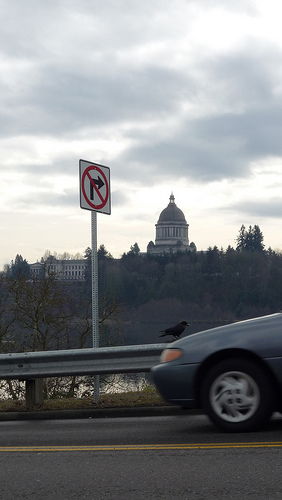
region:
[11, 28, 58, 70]
white clouds in blue sky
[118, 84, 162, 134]
white clouds in blue sky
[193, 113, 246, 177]
white clouds in blue sky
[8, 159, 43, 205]
white clouds in blue sky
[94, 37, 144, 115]
white clouds in blue sky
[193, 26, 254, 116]
white clouds in blue sky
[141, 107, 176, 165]
white clouds in blue sky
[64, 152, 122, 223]
black white and red sign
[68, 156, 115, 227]
black red and white sign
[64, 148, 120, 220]
red white and black sign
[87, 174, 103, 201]
black arrow on white sign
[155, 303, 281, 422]
gray car driving down the street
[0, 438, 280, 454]
yellow double line on street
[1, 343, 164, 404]
metal railing beside street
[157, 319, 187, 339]
black bird perched on metal rail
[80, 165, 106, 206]
red circle on white sign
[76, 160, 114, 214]
white sign with black edges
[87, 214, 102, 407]
metal pole sign is affixed to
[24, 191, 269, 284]
building behind line of trees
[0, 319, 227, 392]
body of water beside roadway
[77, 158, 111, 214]
red white and black sign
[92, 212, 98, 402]
grey metal pole for sign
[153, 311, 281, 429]
grey car on street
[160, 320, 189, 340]
black bird on railing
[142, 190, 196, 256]
capitol building on hill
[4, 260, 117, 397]
tree with green leaves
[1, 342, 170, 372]
grey metal railing by road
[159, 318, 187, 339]
crow sitting on railing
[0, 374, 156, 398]
water next to road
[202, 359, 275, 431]
black tire on car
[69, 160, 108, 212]
street sign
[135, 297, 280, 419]
black car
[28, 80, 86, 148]
white clouds in blue sky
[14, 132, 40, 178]
white clouds in blue sky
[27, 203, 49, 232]
white clouds in blue sky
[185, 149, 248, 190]
white clouds in blue sky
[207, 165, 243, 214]
white clouds in blue sky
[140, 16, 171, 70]
white clouds in blue sky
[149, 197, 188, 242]
large white and brown building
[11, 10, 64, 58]
white clouds in blue sky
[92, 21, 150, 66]
white clouds in blue sky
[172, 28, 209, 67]
white clouds in blue sky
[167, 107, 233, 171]
white clouds in blue sky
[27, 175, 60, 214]
white clouds in blue sky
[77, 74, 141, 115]
white clouds in blue sky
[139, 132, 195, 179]
white clouds in blue sky